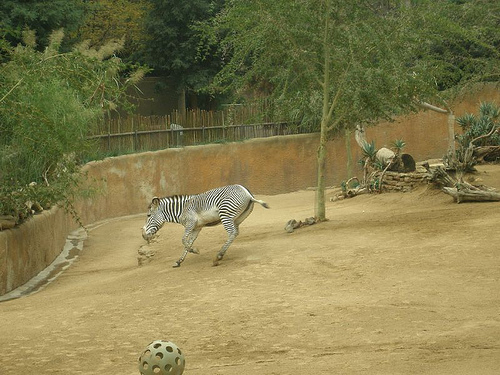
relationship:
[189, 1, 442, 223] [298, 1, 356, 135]
tree has branches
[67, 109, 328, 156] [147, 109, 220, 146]
fence made of sticks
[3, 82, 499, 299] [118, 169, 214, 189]
wall made of stone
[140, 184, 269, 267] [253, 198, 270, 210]
zebra has a tail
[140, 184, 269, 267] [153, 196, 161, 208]
zebra has an ear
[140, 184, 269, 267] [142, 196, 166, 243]
zebra has a head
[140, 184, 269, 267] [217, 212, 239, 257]
zebra has a leg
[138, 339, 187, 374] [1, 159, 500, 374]
ball laying on dirt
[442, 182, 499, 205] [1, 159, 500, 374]
log laying on dirt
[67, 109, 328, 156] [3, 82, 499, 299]
fence behind wall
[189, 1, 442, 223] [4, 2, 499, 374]
tree inside enclosure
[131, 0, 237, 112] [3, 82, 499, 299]
tree outside of wall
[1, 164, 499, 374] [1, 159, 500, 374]
dirt covering dirt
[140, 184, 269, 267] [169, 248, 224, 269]
zebra has feet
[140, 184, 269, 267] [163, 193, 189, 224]
zebra has a neck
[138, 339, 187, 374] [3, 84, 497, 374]
ball inside of pen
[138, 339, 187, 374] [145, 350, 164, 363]
ball has holes